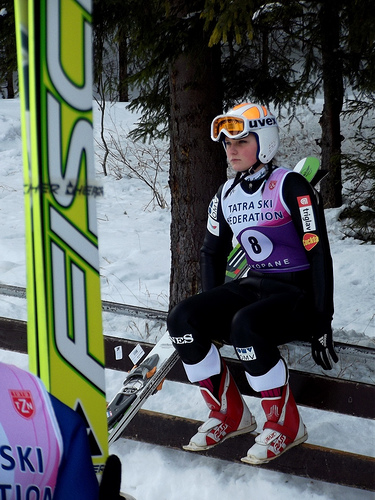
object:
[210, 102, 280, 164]
helmet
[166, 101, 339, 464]
woman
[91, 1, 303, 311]
tree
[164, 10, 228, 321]
trunk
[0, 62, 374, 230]
snow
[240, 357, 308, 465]
shoes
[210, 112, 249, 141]
goggles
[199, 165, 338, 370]
top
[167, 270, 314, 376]
pants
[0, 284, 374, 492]
ledge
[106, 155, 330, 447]
skis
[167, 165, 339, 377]
snow suit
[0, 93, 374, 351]
ground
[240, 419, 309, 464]
feet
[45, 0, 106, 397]
words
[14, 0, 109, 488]
gear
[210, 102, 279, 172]
head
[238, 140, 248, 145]
eyes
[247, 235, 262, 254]
number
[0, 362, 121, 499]
skier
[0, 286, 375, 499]
foreground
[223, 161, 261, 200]
strap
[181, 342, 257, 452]
boots